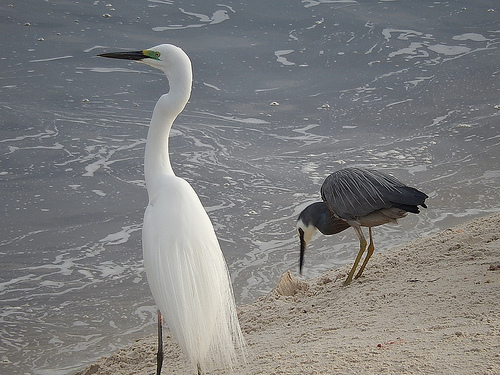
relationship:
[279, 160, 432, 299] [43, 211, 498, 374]
bird in sand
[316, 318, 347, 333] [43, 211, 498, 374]
tracks in sand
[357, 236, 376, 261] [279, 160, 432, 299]
knees on bird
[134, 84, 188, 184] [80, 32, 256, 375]
neck on heron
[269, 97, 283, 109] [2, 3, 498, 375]
bubbles in water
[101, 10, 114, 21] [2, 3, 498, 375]
bubbles in water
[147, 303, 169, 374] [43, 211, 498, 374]
legs in sand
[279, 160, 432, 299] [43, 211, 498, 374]
bird pecking sand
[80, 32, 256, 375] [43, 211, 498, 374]
heron on sand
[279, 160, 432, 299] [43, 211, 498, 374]
bird on sand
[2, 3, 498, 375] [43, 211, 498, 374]
water by sand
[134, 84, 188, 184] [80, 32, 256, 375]
neck of heron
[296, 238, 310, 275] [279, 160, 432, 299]
beak on bird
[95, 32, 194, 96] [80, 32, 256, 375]
head of heron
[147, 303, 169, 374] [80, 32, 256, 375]
legs of heron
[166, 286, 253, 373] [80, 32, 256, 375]
feathers of heron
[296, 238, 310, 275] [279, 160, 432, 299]
beak of bird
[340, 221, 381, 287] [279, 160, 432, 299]
legs of bird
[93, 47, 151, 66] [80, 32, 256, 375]
beak of heron